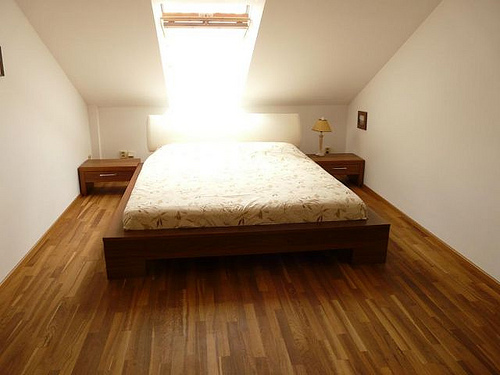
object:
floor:
[2, 182, 499, 375]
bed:
[102, 113, 389, 283]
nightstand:
[77, 157, 137, 196]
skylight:
[154, 23, 263, 104]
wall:
[2, 1, 95, 300]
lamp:
[311, 117, 334, 157]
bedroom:
[1, 2, 499, 374]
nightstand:
[306, 154, 366, 184]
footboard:
[101, 221, 396, 280]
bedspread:
[124, 139, 368, 227]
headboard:
[147, 112, 302, 145]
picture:
[355, 109, 371, 134]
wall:
[344, 0, 500, 281]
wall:
[88, 101, 349, 159]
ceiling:
[0, 0, 500, 109]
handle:
[98, 171, 115, 178]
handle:
[333, 165, 347, 170]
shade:
[312, 117, 331, 131]